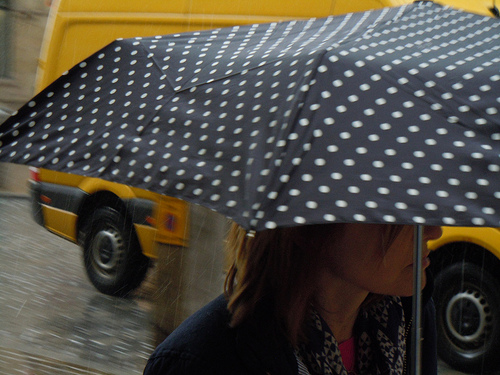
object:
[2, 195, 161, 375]
water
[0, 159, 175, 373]
asphalt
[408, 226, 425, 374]
post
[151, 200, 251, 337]
gray rims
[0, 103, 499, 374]
rain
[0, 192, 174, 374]
ground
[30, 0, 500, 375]
car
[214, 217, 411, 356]
hair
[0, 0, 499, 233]
polka dots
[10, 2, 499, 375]
umbrella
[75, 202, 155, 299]
tire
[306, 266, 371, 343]
neck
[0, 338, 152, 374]
sidewalk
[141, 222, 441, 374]
person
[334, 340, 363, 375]
pink shirt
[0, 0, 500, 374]
street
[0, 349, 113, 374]
corner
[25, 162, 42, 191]
reflector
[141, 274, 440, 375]
coat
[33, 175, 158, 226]
trim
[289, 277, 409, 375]
scarf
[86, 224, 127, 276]
rim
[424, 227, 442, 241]
woman's nose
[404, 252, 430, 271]
lips